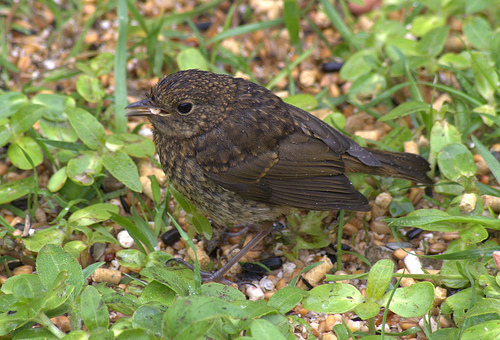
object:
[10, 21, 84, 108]
rocks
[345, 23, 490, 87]
grass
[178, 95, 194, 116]
eye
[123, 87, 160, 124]
beak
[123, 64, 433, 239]
bird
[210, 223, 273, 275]
legs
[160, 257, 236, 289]
feet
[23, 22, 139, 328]
ground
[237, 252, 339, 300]
seed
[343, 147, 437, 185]
tail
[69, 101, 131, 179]
leaves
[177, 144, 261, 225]
feathers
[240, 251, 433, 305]
food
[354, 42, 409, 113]
tip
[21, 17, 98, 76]
debris